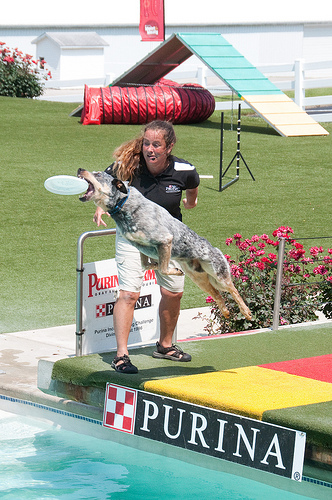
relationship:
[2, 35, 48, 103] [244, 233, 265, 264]
bush with flowers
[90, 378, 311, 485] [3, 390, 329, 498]
purina sign in front of pool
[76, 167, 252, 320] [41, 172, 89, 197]
animal jumping for frisbee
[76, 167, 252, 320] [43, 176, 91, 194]
animal with batter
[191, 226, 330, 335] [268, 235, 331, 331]
flower near fence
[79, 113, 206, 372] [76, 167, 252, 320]
lady near animal